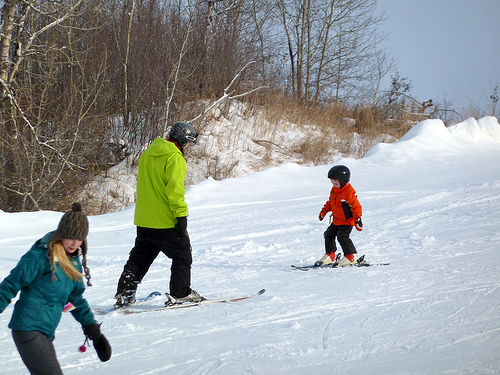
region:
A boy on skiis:
[285, 133, 421, 310]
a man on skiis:
[113, 80, 243, 331]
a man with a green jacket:
[95, 80, 259, 325]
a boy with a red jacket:
[268, 123, 398, 313]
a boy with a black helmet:
[272, 111, 391, 309]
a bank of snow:
[349, 80, 483, 165]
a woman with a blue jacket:
[2, 180, 120, 367]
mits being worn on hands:
[59, 310, 136, 362]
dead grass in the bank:
[242, 74, 341, 157]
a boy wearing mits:
[334, 212, 385, 239]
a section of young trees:
[2, 0, 394, 115]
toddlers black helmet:
[323, 159, 354, 192]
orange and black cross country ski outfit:
[316, 181, 369, 263]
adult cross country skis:
[98, 288, 285, 312]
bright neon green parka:
[130, 134, 187, 232]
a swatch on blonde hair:
[46, 241, 83, 286]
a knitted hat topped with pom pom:
[46, 191, 93, 293]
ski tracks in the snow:
[198, 175, 311, 335]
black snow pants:
[110, 226, 203, 304]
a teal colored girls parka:
[2, 232, 94, 339]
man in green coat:
[118, 118, 205, 306]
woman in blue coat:
[2, 199, 115, 372]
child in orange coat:
[315, 162, 368, 267]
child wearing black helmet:
[325, 162, 352, 186]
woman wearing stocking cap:
[48, 199, 93, 290]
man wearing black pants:
[115, 225, 193, 296]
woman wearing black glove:
[81, 320, 113, 362]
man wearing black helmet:
[170, 120, 196, 144]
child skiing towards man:
[318, 164, 364, 266]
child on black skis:
[291, 262, 389, 269]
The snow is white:
[332, 304, 390, 372]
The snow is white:
[287, 320, 319, 364]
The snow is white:
[324, 360, 351, 371]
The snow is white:
[326, 352, 338, 368]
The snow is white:
[296, 296, 326, 343]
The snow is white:
[324, 311, 377, 359]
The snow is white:
[346, 324, 354, 366]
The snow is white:
[309, 368, 319, 370]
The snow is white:
[328, 311, 356, 353]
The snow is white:
[348, 283, 413, 338]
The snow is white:
[321, 287, 363, 349]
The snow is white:
[335, 290, 375, 340]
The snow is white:
[326, 360, 331, 366]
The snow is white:
[358, 311, 381, 343]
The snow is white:
[322, 335, 351, 368]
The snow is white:
[358, 330, 380, 364]